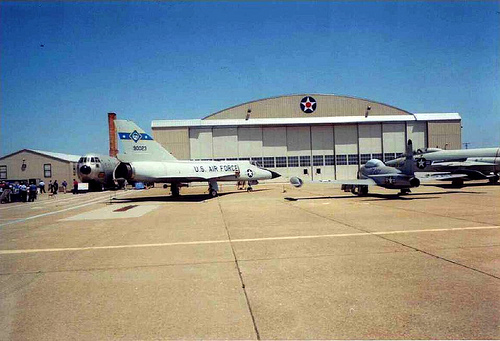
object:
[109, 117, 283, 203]
plane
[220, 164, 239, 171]
writing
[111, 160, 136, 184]
afterburner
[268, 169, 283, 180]
nose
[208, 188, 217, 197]
wheel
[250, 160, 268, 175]
cockpit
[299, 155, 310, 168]
window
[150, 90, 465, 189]
plane hanger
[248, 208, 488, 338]
cement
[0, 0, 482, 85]
sky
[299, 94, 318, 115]
logo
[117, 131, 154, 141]
stripe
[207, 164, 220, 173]
words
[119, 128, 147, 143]
sign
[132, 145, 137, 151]
numbers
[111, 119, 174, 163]
tail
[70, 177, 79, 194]
people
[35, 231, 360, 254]
line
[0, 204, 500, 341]
floor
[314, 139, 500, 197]
plane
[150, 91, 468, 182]
building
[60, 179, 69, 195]
people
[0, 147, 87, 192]
building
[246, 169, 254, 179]
logotype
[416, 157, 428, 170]
logotype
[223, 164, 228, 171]
letter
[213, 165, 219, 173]
letter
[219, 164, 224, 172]
letter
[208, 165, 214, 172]
letter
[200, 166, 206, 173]
letter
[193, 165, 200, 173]
letter